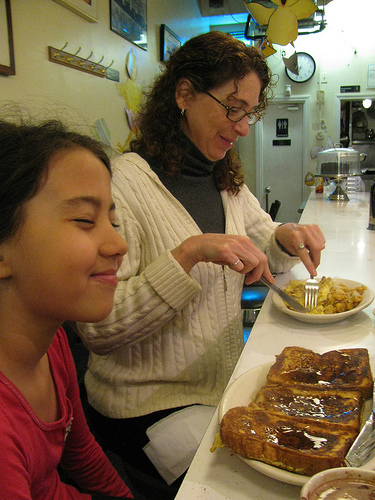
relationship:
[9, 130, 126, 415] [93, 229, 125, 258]
girl has nose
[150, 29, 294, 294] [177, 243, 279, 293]
woman has hand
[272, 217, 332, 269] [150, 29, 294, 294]
hand of woman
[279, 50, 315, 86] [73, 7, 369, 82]
clock on wall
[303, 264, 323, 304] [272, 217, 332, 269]
fork in hand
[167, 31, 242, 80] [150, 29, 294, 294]
hair on woman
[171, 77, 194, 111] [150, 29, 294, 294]
ear of woman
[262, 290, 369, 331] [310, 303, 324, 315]
bowl has food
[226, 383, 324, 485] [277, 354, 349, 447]
plate has french toast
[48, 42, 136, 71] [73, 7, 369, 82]
hooks on wall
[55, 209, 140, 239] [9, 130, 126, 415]
eyes on girl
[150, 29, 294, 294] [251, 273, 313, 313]
woman holding knife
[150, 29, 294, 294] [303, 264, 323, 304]
woman holding fork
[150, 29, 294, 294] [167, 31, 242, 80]
woman has hair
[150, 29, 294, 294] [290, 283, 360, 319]
woman cutting food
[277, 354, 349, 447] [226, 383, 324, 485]
french toast on plate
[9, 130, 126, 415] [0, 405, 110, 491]
girl wearing shirt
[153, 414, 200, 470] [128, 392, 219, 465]
napkin on lap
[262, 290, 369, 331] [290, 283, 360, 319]
bowl has food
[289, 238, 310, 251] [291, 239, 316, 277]
ring on finger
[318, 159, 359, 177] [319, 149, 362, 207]
cake on stand